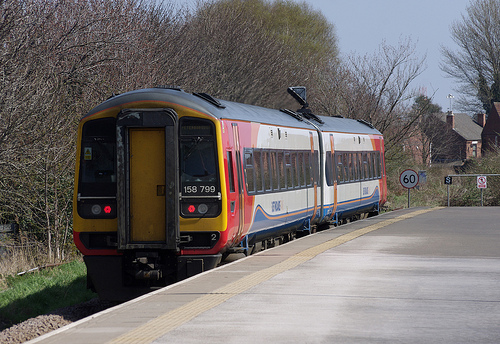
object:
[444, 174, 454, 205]
metal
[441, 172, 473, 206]
fencing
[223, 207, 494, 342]
pedway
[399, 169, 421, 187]
metal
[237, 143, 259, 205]
window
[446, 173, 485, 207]
fence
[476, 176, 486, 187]
sign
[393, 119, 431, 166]
house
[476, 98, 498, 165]
house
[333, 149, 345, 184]
window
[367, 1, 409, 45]
sky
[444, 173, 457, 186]
sign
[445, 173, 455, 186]
number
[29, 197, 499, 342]
sidewalk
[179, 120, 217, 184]
window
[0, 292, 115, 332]
train track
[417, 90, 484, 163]
house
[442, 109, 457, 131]
chimney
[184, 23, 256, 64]
branches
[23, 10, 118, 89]
branches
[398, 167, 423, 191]
sign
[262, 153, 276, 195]
window train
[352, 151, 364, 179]
window train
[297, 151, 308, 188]
window train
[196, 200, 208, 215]
light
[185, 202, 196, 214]
light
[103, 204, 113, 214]
light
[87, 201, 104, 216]
light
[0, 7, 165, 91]
trees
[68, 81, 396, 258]
tracks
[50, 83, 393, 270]
train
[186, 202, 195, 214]
red light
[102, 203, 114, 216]
red light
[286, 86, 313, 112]
antenna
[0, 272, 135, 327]
shadow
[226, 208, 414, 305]
line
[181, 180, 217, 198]
numbers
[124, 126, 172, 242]
door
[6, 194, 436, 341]
track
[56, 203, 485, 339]
concrete